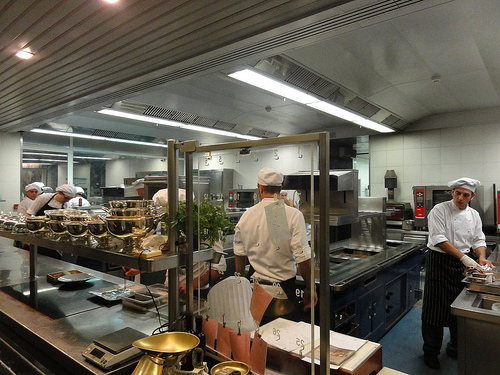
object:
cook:
[422, 177, 496, 370]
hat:
[447, 177, 480, 192]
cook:
[233, 167, 310, 320]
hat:
[258, 167, 284, 186]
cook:
[18, 185, 38, 219]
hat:
[25, 184, 39, 191]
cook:
[27, 184, 76, 216]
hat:
[56, 184, 76, 197]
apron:
[420, 253, 466, 323]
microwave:
[413, 185, 484, 226]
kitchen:
[3, 3, 496, 372]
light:
[228, 68, 395, 133]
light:
[97, 107, 263, 140]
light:
[30, 129, 167, 148]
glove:
[460, 255, 484, 272]